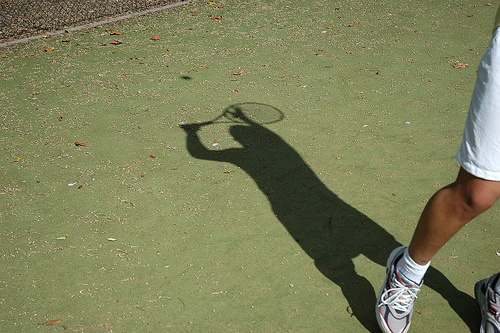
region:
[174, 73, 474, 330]
this is a shadow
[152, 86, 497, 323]
shadow of a person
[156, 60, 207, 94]
shadow of a ball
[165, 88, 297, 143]
shadow of a tennis racket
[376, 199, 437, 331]
this is a shoe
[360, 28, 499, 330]
this is a leg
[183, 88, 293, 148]
shadow of tennis racket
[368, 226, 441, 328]
person wearing tennis shoes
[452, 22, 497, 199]
person wearing white shorts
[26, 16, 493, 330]
the ground is green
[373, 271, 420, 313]
white laces on shoes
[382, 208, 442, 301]
person wearing white socks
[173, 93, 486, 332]
Tennis player's shadow.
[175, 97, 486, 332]
Shadow of a person with a tennis racket.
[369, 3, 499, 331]
Person in white shorts and athletic shoes.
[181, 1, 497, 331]
A person and their shadow.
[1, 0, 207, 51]
Wire fence.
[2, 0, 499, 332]
Tennis court.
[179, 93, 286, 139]
Shadow of a tennis racket.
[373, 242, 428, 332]
Athletic shoe and white sock.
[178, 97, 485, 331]
Shadow with a tennis racket over its head.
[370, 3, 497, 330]
Person that is casting a shadow.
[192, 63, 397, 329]
shadow on the ground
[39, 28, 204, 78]
leaves on the court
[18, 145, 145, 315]
dirt on the court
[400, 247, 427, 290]
the sock is white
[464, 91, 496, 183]
the shorts are white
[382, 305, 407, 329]
lines on the shoe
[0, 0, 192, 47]
part of chain-link fence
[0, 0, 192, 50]
black chain-link fence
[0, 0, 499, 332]
part of tennis court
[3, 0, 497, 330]
green tennis court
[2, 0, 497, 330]
ground is dirty and covered in leaves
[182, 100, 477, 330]
shadow of tennis player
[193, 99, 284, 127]
shadow of tennis racket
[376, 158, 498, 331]
legs of tennis player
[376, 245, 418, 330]
a gray and blue sneaker shoe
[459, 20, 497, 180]
part of white tennis shorts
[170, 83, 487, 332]
shadow of tennis player on ground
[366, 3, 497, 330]
person jumping in air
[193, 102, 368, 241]
a shadow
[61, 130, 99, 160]
a small leaf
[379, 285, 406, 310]
shoe laces are white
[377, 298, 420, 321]
a shoe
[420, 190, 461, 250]
a persons leg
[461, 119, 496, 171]
shorts are white